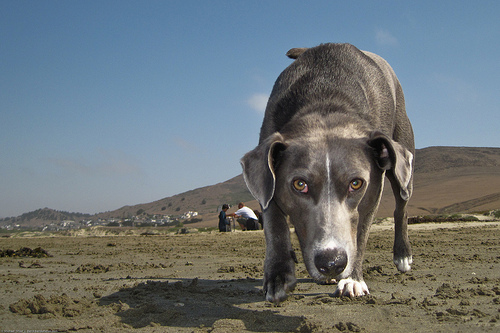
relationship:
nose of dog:
[304, 243, 356, 278] [231, 35, 428, 310]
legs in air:
[257, 202, 307, 316] [38, 18, 160, 103]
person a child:
[217, 204, 232, 234] [217, 198, 231, 232]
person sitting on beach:
[218, 204, 235, 229] [1, 221, 498, 331]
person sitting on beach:
[235, 201, 260, 229] [1, 221, 498, 331]